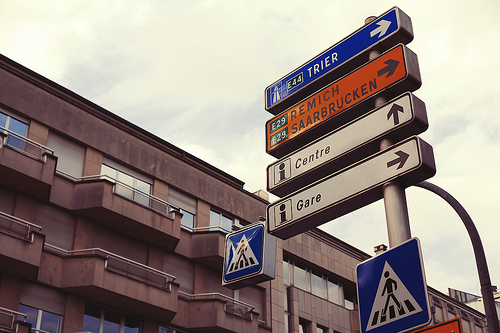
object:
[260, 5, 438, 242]
stack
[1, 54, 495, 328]
building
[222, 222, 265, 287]
sign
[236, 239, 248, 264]
walk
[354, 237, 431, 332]
sign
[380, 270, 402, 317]
walk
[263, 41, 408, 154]
sign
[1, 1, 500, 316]
sky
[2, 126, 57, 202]
balcony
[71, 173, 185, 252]
balcony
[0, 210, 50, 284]
balcony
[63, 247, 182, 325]
balcony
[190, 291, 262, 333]
balcony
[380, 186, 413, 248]
pole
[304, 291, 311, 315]
tile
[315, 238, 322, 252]
tile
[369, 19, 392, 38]
arrow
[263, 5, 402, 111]
sign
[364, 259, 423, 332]
triangle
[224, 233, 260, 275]
triangle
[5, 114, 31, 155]
window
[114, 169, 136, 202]
window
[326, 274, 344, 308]
window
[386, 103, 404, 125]
arrow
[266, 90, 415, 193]
sign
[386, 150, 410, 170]
arrow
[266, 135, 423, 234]
sign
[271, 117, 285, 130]
e29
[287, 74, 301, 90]
e44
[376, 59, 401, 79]
arrow